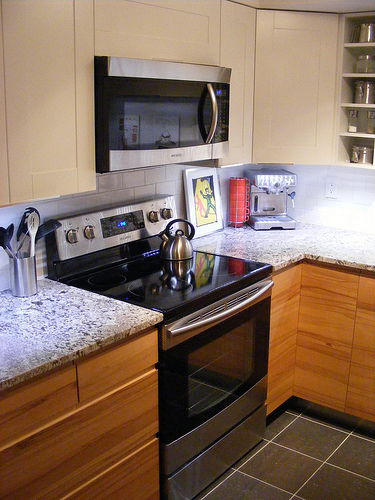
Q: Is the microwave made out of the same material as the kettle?
A: Yes, both the microwave and the kettle are made of metal.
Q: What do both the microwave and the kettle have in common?
A: The material, both the microwave and the kettle are metallic.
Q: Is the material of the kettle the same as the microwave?
A: Yes, both the kettle and the microwave are made of metal.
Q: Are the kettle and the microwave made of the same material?
A: Yes, both the kettle and the microwave are made of metal.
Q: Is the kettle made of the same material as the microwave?
A: Yes, both the kettle and the microwave are made of metal.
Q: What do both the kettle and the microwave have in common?
A: The material, both the kettle and the microwave are metallic.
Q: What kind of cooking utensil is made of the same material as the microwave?
A: The kettle is made of the same material as the microwave.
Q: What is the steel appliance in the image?
A: The appliance is a stove.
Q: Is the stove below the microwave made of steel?
A: Yes, the stove is made of steel.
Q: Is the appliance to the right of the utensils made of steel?
A: Yes, the stove is made of steel.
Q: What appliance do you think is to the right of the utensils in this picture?
A: The appliance is a stove.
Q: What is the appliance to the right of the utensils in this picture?
A: The appliance is a stove.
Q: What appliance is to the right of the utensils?
A: The appliance is a stove.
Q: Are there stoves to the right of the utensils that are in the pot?
A: Yes, there is a stove to the right of the utensils.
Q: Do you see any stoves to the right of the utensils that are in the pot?
A: Yes, there is a stove to the right of the utensils.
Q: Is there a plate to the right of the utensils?
A: No, there is a stove to the right of the utensils.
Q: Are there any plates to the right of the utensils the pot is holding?
A: No, there is a stove to the right of the utensils.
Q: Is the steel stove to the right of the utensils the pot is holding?
A: Yes, the stove is to the right of the utensils.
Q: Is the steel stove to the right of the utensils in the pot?
A: Yes, the stove is to the right of the utensils.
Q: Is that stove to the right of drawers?
A: No, the stove is to the right of the utensils.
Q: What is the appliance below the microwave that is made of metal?
A: The appliance is a stove.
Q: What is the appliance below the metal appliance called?
A: The appliance is a stove.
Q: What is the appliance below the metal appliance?
A: The appliance is a stove.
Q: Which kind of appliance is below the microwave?
A: The appliance is a stove.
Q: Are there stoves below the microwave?
A: Yes, there is a stove below the microwave.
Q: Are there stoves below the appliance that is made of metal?
A: Yes, there is a stove below the microwave.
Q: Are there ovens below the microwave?
A: No, there is a stove below the microwave.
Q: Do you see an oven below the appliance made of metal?
A: No, there is a stove below the microwave.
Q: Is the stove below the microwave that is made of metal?
A: Yes, the stove is below the microwave.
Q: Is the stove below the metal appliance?
A: Yes, the stove is below the microwave.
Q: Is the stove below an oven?
A: No, the stove is below the microwave.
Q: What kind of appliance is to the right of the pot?
A: The appliance is a stove.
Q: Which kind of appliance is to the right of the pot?
A: The appliance is a stove.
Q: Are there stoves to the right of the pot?
A: Yes, there is a stove to the right of the pot.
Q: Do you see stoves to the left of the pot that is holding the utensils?
A: No, the stove is to the right of the pot.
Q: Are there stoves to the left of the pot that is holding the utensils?
A: No, the stove is to the right of the pot.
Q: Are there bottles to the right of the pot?
A: No, there is a stove to the right of the pot.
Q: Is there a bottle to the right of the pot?
A: No, there is a stove to the right of the pot.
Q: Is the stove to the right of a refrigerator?
A: No, the stove is to the right of a pot.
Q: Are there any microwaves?
A: Yes, there is a microwave.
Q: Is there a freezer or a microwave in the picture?
A: Yes, there is a microwave.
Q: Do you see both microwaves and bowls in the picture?
A: No, there is a microwave but no bowls.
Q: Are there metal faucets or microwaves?
A: Yes, there is a metal microwave.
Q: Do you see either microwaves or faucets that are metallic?
A: Yes, the microwave is metallic.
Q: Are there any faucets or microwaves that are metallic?
A: Yes, the microwave is metallic.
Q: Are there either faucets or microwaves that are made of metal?
A: Yes, the microwave is made of metal.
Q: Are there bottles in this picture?
A: No, there are no bottles.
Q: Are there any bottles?
A: No, there are no bottles.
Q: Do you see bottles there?
A: No, there are no bottles.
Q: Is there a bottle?
A: No, there are no bottles.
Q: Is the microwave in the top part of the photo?
A: Yes, the microwave is in the top of the image.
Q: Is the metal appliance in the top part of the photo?
A: Yes, the microwave is in the top of the image.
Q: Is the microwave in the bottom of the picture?
A: No, the microwave is in the top of the image.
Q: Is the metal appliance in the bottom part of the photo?
A: No, the microwave is in the top of the image.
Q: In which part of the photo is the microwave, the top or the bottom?
A: The microwave is in the top of the image.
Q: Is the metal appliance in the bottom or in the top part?
A: The microwave is in the top of the image.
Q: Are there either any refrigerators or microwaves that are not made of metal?
A: No, there is a microwave but it is made of metal.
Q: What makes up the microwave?
A: The microwave is made of metal.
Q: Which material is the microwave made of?
A: The microwave is made of metal.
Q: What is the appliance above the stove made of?
A: The microwave is made of metal.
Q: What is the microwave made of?
A: The microwave is made of metal.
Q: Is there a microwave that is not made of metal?
A: No, there is a microwave but it is made of metal.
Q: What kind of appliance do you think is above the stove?
A: The appliance is a microwave.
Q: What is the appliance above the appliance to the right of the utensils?
A: The appliance is a microwave.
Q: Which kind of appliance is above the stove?
A: The appliance is a microwave.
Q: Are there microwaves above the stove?
A: Yes, there is a microwave above the stove.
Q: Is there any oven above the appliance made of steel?
A: No, there is a microwave above the stove.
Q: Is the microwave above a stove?
A: Yes, the microwave is above a stove.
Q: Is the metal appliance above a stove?
A: Yes, the microwave is above a stove.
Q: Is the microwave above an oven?
A: No, the microwave is above a stove.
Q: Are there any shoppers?
A: No, there are no shoppers.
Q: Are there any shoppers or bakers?
A: No, there are no shoppers or bakers.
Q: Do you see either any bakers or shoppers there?
A: No, there are no shoppers or bakers.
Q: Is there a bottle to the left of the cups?
A: No, there is a man to the left of the cups.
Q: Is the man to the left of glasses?
A: No, the man is to the left of the cups.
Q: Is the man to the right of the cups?
A: No, the man is to the left of the cups.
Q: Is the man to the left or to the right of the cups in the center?
A: The man is to the left of the cups.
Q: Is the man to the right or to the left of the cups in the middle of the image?
A: The man is to the left of the cups.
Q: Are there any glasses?
A: No, there are no glasses.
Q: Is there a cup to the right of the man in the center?
A: Yes, there are cups to the right of the man.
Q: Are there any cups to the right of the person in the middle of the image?
A: Yes, there are cups to the right of the man.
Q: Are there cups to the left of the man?
A: No, the cups are to the right of the man.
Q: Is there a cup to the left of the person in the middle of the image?
A: No, the cups are to the right of the man.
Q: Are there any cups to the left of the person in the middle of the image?
A: No, the cups are to the right of the man.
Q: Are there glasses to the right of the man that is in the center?
A: No, there are cups to the right of the man.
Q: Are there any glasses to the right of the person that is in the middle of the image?
A: No, there are cups to the right of the man.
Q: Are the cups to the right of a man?
A: Yes, the cups are to the right of a man.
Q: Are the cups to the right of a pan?
A: No, the cups are to the right of a man.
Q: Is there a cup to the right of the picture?
A: Yes, there are cups to the right of the picture.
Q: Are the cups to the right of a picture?
A: Yes, the cups are to the right of a picture.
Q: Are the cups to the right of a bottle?
A: No, the cups are to the right of a picture.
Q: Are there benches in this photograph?
A: No, there are no benches.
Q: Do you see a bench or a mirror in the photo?
A: No, there are no benches or mirrors.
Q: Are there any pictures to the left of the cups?
A: Yes, there is a picture to the left of the cups.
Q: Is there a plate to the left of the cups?
A: No, there is a picture to the left of the cups.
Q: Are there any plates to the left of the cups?
A: No, there is a picture to the left of the cups.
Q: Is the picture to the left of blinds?
A: No, the picture is to the left of the cups.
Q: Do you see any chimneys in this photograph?
A: No, there are no chimneys.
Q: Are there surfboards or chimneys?
A: No, there are no chimneys or surfboards.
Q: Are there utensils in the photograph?
A: Yes, there are utensils.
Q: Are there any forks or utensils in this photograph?
A: Yes, there are utensils.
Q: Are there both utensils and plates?
A: No, there are utensils but no plates.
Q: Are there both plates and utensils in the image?
A: No, there are utensils but no plates.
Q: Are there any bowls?
A: No, there are no bowls.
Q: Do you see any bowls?
A: No, there are no bowls.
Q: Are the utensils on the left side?
A: Yes, the utensils are on the left of the image.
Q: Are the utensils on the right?
A: No, the utensils are on the left of the image.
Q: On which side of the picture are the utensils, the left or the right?
A: The utensils are on the left of the image.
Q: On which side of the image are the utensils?
A: The utensils are on the left of the image.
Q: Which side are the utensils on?
A: The utensils are on the left of the image.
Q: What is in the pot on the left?
A: The utensils are in the pot.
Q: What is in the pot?
A: The utensils are in the pot.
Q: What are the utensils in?
A: The utensils are in the pot.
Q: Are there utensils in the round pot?
A: Yes, there are utensils in the pot.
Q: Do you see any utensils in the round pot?
A: Yes, there are utensils in the pot.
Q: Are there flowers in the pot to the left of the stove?
A: No, there are utensils in the pot.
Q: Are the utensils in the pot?
A: Yes, the utensils are in the pot.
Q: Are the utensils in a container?
A: No, the utensils are in the pot.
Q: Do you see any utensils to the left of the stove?
A: Yes, there are utensils to the left of the stove.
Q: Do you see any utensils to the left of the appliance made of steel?
A: Yes, there are utensils to the left of the stove.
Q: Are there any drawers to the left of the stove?
A: No, there are utensils to the left of the stove.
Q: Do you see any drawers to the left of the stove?
A: No, there are utensils to the left of the stove.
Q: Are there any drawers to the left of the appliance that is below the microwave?
A: No, there are utensils to the left of the stove.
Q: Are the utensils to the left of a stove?
A: Yes, the utensils are to the left of a stove.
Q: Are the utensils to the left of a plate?
A: No, the utensils are to the left of a stove.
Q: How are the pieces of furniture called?
A: The pieces of furniture are cabinets.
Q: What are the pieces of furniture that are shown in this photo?
A: The pieces of furniture are cabinets.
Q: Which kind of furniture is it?
A: The pieces of furniture are cabinets.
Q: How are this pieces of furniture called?
A: These are cabinets.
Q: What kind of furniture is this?
A: These are cabinets.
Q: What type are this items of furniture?
A: These are cabinets.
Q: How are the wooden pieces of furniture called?
A: The pieces of furniture are cabinets.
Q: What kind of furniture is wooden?
A: The furniture is cabinets.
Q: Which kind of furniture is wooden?
A: The furniture is cabinets.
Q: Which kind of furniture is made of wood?
A: The furniture is cabinets.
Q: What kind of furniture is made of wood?
A: The furniture is cabinets.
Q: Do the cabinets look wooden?
A: Yes, the cabinets are wooden.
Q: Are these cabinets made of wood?
A: Yes, the cabinets are made of wood.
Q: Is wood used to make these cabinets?
A: Yes, the cabinets are made of wood.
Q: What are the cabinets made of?
A: The cabinets are made of wood.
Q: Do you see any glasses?
A: No, there are no glasses.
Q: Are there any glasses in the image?
A: No, there are no glasses.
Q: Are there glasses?
A: No, there are no glasses.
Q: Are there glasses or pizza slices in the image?
A: No, there are no glasses or pizza slices.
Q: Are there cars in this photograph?
A: No, there are no cars.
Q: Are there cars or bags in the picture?
A: No, there are no cars or bags.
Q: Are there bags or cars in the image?
A: No, there are no cars or bags.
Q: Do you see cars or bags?
A: No, there are no cars or bags.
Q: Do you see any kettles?
A: Yes, there is a kettle.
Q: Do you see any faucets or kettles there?
A: Yes, there is a kettle.